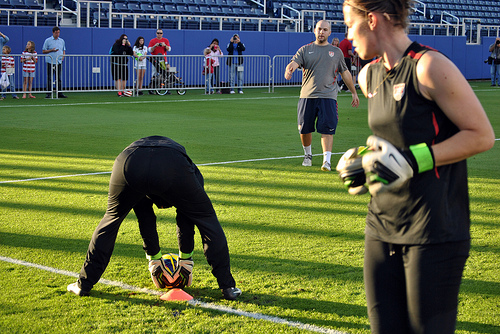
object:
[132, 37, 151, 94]
person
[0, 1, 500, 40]
stands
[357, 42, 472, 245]
tanktop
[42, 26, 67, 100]
person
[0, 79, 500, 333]
field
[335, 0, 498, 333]
person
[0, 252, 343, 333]
line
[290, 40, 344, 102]
t-shirt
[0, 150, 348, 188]
white line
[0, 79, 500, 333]
grass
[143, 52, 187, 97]
stroller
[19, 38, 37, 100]
person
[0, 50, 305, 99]
fence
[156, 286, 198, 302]
cone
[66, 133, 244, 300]
man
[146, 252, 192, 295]
ball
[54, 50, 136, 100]
gate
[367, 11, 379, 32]
ear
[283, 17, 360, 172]
man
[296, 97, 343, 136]
shorts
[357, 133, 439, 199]
glove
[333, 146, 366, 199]
glove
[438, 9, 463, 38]
handrail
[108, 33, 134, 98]
person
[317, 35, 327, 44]
beard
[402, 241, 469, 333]
leg